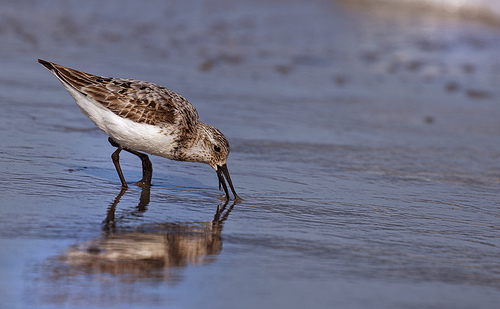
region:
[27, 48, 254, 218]
Bird is searching on sand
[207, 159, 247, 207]
Beck of bird is black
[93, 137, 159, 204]
Legs of bird are on wet sand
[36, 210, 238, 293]
Bird reflection on sand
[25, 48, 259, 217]
Bird is brown and white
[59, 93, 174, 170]
Chest of bird is white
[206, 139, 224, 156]
Eye of birth is black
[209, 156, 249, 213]
Beck of bird is open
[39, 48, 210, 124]
Wings of bird are brown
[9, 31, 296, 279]
Bird is on wet sand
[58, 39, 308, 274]
a bird with it's mouth in the water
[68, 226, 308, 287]
reflection in the water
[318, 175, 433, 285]
water is there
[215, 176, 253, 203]
the beak of the bird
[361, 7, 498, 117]
rock in the water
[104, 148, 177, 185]
the legs of the bird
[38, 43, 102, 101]
the tail of the bird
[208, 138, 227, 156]
the eye of the bird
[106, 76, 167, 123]
the feather of the birds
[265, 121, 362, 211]
waves in the water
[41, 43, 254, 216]
bird on the beach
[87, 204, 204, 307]
reflection of the bird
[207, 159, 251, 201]
beak on the bird's face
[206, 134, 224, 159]
black eye of the bird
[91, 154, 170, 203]
two legs of the bird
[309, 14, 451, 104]
fuzzy background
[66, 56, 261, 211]
brown and white bird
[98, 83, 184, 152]
feathers on the side of the bird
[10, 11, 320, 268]
bird getting a drink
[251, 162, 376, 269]
water on the ground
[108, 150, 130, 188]
Bird's leg is black.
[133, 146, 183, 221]
Bird's leg is black.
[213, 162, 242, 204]
Bird's beak is black.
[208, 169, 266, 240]
Tip of bird's beak is in water.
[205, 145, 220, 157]
Bird has a dark eye.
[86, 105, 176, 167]
Bird has a white chest.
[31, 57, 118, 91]
Bird has brown tail feathers.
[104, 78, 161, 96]
Bird has brown wings.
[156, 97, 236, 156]
Bird has brown and gray head.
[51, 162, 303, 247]
Bird is standing in water.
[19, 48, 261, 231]
Brown and white bird on sand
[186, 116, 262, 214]
Bird searching with beak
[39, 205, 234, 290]
Reflection on wet sand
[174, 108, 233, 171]
Head and neck of bird are brown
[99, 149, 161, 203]
Legs of bird is orange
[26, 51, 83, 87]
Tail of bird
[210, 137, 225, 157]
Eye of bird is black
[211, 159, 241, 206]
Beak is open